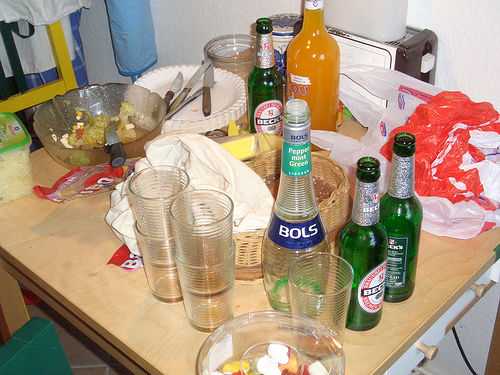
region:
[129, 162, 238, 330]
Empty used glasses on the table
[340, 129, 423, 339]
Beer bottles on the table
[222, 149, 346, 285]
Wicker basket on the table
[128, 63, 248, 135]
Stack of paper plates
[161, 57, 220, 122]
Knives on the paper plates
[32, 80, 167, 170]
Leftover food in a glass bowl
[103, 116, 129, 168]
Knife in the bowl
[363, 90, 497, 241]
Plastic bags on the table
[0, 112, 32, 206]
Plastic container with green top on the table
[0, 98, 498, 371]
Wooden table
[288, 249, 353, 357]
A glass on a table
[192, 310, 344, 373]
Bowl of food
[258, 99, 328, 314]
Bottle of a drink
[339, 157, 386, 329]
Green bottle of beer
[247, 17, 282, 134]
Bottle filled with beer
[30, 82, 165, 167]
A glass bowl sitting on a table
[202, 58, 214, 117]
A knife on a plate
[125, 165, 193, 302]
A stack of glasses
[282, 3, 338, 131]
A bottle of an orange drink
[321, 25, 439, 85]
A toaster on a table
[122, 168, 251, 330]
The glasses on the table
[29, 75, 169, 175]
The bowl on the table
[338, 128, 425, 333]
The bottle on the table are green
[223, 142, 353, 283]
The wicker bowl on the table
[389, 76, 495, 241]
The bags on the table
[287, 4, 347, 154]
The bottle of orange drink on the table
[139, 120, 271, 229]
The white cloth in the basket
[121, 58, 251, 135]
A stack of paper plates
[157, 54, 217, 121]
Knives on the paper plates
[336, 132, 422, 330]
green Beck's beer bottles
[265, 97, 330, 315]
BOLS bottled water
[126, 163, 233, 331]
empty plastic party glasses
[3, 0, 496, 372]
table filled with empty bottles, leftover party food, drink, and dinner ware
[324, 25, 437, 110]
toaster with white plastic lever handle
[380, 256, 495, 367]
drawers under butcher block table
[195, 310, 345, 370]
appetizer leftovers in covered dish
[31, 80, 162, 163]
half-full large salad bowl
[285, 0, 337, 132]
bottle of orange beverage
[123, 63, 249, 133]
stack of paper plates and metal silverware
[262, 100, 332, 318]
an empty glass botte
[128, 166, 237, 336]
four empty glasses stacked up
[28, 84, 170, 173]
a nearly empty bowl of salad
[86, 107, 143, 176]
a knife leaning across the edge of a bowl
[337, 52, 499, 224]
a plastic shopping bag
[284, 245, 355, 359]
an empty drinking glass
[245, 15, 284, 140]
am empty bottle of Beck's beer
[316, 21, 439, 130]
a black and white toaster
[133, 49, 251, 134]
a stack of paper plates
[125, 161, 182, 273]
glass on the wooden table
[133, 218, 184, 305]
glass on the wooden table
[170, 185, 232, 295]
glass on the wooden table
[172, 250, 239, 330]
glass on the wooden table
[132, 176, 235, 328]
Glass cups stacked up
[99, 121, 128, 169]
A black handled knife.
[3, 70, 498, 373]
A light brown wooden table.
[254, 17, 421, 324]
Green beer bottles.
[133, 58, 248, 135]
A stack of white paper plates.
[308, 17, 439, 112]
A silver and black toaster.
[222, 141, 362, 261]
A light brown woven basket.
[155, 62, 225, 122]
Knives resting on top of a stack of paper plates.